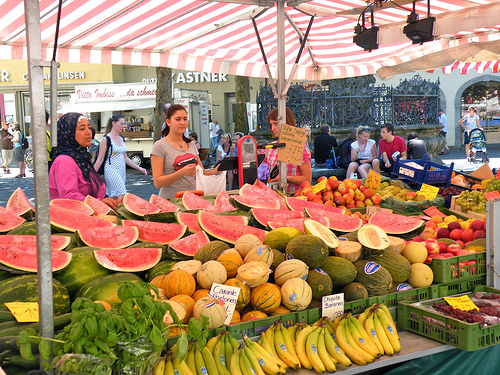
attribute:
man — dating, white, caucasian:
[379, 122, 403, 172]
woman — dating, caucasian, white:
[347, 126, 377, 173]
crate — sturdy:
[398, 289, 498, 350]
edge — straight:
[396, 300, 469, 347]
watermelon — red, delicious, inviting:
[83, 247, 163, 272]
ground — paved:
[426, 158, 463, 192]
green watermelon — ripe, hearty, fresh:
[92, 244, 164, 268]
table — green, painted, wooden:
[404, 343, 448, 368]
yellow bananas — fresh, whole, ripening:
[247, 325, 345, 371]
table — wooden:
[283, 324, 457, 374]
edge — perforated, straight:
[433, 327, 442, 337]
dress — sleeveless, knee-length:
[92, 124, 146, 192]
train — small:
[388, 150, 459, 186]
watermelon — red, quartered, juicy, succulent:
[4, 181, 433, 275]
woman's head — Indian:
[53, 108, 98, 160]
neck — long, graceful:
[51, 135, 91, 162]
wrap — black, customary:
[56, 117, 79, 158]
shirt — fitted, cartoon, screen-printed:
[147, 131, 194, 192]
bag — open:
[187, 163, 234, 195]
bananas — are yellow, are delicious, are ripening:
[149, 285, 450, 363]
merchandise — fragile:
[435, 300, 476, 319]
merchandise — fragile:
[443, 284, 483, 325]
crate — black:
[394, 157, 457, 188]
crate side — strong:
[395, 161, 418, 179]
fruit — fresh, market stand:
[410, 159, 425, 171]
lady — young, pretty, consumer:
[148, 102, 202, 199]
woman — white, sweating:
[98, 109, 134, 201]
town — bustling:
[3, 40, 478, 201]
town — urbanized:
[21, 75, 484, 195]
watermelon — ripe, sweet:
[5, 239, 85, 276]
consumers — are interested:
[32, 106, 319, 180]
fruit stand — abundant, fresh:
[3, 169, 483, 358]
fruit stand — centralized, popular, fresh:
[5, 132, 481, 353]